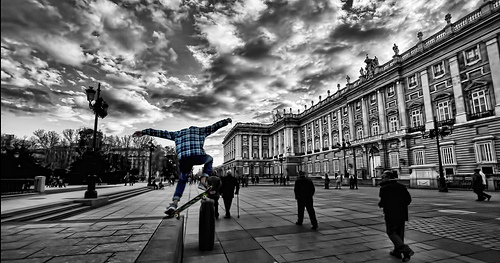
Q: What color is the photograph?
A: Black and white.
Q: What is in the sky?
A: Clouds.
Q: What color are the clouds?
A: Grey.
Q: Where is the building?
A: Alongside the road.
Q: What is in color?
A: The skater's plaid jacket.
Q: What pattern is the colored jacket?
A: Plaid.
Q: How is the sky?
A: Cloudy.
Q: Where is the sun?
A: Behind the clouds.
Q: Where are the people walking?
A: On the sidewalk.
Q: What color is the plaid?
A: Blue.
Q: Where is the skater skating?
A: On the curb.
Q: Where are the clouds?
A: In the sky.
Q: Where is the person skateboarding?
A: At the park.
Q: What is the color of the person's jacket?
A: Blue.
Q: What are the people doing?
A: Walking.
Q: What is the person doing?
A: Skateboarding.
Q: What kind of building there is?
A: An abbey.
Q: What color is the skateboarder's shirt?
A: Blue plaid.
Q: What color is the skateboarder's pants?
A: Blue.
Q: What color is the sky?
A: Monochrome.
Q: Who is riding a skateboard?
A: The person in blue.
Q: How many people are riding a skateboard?
A: One.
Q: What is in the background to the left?
A: Trees.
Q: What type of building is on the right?
A: Apartment building.